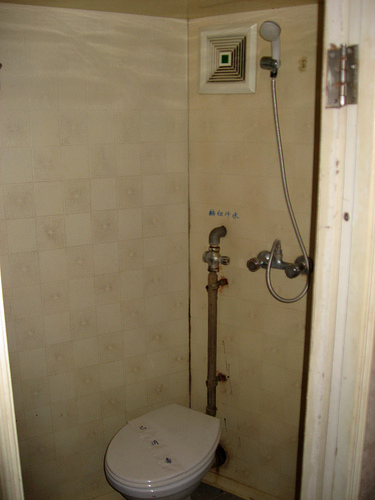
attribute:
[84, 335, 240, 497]
toilet — white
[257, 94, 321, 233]
hose — flexible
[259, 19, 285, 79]
shower head — white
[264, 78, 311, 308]
piping — silver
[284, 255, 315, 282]
valve — cold water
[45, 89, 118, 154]
wall — rust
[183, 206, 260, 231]
writing — blue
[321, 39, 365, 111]
hinge — silver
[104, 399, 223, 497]
toilet — old, white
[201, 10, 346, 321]
head — shower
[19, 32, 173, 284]
wall — dirty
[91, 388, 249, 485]
toilet — dirty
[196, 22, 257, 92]
vent — built 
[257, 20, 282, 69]
shower head — silver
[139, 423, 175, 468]
writing — blue